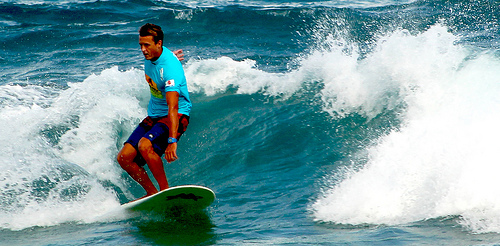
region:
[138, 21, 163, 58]
Small tan human head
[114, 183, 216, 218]
Long large white surf board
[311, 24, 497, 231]
Frothy white wave foam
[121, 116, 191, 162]
Long cloth blue shirts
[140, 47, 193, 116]
small blue cloth shirt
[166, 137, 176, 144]
small blue wrist watch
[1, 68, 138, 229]
Large crashing white wave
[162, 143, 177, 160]
small tan human hand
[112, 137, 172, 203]
Long tan human legs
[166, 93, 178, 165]
Long tan skinny human arm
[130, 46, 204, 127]
MAN IS WEARING A LIGHT BLUE SHIRT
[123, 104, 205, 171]
SHORTS ARE RED AND BLUE IN COLOR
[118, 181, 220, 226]
SURF BOARD IS ON TOP OF WATER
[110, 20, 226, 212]
MAN IS ON TOP OF SURFBOARD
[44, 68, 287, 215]
SURFER IS RIDING A WAVE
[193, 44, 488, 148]
WHITE CAPS ARE ON TOP OF THE WAVES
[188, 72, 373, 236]
WATER IS OF A BLUE GREEN COLOR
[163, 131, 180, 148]
MAN IS WEARING A WATCH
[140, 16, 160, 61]
MAN HAS SHORT BROWN HAIR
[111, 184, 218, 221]
BOARD IS WHITE IN COLOR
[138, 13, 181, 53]
Man has brown hair.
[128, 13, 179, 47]
Man has short hair.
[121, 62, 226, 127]
Man wearing blue shirt.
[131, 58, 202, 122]
Man wearing t-shirt.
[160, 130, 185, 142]
Blue band around man's wrist.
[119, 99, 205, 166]
Man wearing blue and red shorts.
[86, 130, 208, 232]
Man standing on surfboard.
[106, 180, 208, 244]
Surfboard is white in color.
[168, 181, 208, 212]
Black markings on bottom of board.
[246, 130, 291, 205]
Water is bright blue.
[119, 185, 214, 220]
long green surf board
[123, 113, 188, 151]
blue and red trunks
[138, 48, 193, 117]
blue cotton tee shirt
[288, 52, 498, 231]
wave breaking on shore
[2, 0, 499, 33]
wave forming in ocean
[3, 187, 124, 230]
white foam in ocean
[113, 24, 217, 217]
man standing on surf board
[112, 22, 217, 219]
man surfing in ocean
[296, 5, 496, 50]
water splashing from wave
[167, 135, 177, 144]
blue watch on wrist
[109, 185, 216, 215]
A mostly white surfboard.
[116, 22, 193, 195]
A brown haired man on a surfboard.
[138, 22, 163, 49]
Brown hair on a man surfing.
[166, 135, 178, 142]
A blue watch on the wrist of a surfer.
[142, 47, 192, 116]
A light blue shirt on a man surfing.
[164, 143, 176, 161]
A left hand of a surfing man.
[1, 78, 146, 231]
White wave behind the surfboard.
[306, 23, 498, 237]
Large white wave to the right of a surfer.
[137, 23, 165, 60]
Head of a surfer with brown hair.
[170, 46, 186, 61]
Right hand of a surfer.